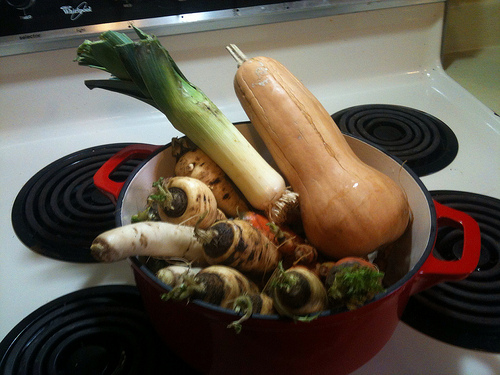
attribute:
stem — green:
[85, 26, 224, 136]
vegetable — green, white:
[73, 25, 298, 224]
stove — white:
[6, 32, 493, 340]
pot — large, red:
[92, 118, 481, 373]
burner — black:
[317, 96, 465, 185]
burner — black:
[333, 99, 458, 162]